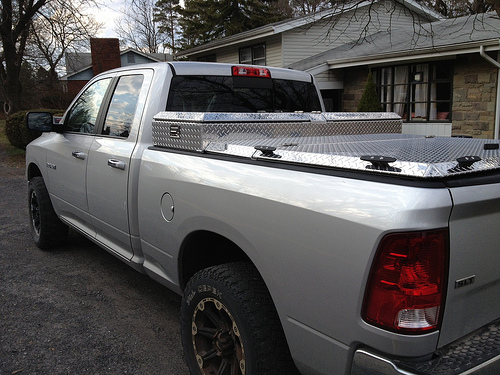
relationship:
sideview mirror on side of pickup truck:
[25, 113, 54, 132] [25, 62, 497, 373]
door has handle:
[86, 68, 154, 259] [105, 159, 126, 170]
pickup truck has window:
[25, 62, 497, 373] [104, 74, 143, 136]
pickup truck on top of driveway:
[25, 62, 497, 373] [1, 143, 190, 374]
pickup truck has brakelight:
[25, 62, 497, 373] [360, 230, 448, 333]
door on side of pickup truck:
[86, 68, 154, 259] [25, 62, 497, 373]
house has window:
[175, 2, 499, 138] [375, 60, 453, 122]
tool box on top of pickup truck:
[151, 110, 401, 150] [25, 62, 497, 373]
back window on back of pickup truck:
[164, 76, 324, 111] [25, 62, 497, 373]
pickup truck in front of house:
[25, 62, 497, 373] [175, 2, 499, 138]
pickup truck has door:
[25, 62, 497, 373] [46, 76, 117, 214]